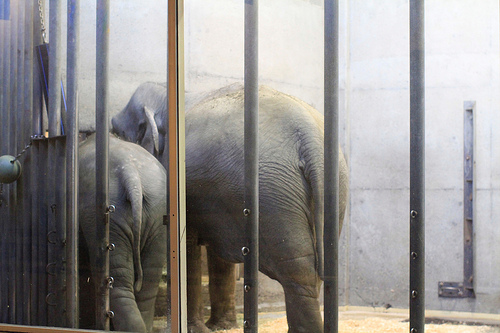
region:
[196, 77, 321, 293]
the elephant is fat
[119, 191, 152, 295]
the elephant has a tail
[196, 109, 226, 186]
the elephant is gray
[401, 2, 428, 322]
the bars are metal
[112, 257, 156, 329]
the elephant has hind legs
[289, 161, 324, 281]
the elephant has a tail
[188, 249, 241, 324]
the elephant has front legs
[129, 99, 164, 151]
the elephant has an ear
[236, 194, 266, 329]
the bar has rings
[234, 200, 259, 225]
the ring is silver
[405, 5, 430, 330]
metal pole of fence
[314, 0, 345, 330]
metal pole of fence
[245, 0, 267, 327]
metal pole of fence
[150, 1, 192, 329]
metal pole of fence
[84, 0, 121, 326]
metal pole of fence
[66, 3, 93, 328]
metal pole of fence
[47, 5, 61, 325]
metal pole of fence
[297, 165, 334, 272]
tail of grey elephant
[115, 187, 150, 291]
tail of grey elephant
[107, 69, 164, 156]
head of grey elephant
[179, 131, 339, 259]
an elephant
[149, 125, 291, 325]
an elephant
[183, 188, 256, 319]
an elephant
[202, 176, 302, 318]
an elephant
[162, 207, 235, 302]
an elephant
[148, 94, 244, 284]
an elephant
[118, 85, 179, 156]
head of the elephant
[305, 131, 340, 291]
tail of the elephant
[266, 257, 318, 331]
leg of the elephant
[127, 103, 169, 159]
ear of the elephant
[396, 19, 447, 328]
a small iron rod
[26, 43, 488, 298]
a series of iron rods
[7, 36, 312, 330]
group of elephants standing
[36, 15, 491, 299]
elephants put into a cage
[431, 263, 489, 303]
a small object on wall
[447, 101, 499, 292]
a small stick placed on wall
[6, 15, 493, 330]
The elephants are in a cage.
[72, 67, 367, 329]
The two elephants are grey.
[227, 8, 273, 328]
A bar on the cage.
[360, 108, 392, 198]
The wal is grey.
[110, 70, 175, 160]
The head of an elephant.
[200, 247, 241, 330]
The front leg of an elephant.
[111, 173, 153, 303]
The tail of an elephant.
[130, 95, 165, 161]
The ear of the elephant.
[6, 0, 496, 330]
Bars are on the elephant enclosure.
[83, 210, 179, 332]
The elephant has two hind legs.